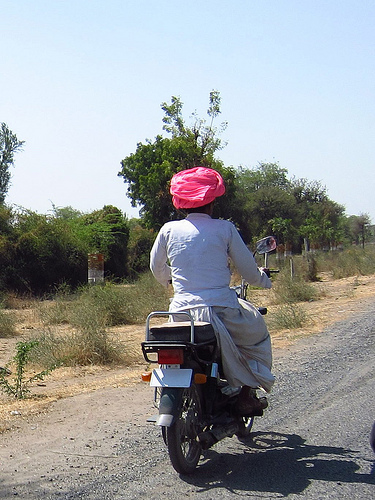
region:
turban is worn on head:
[167, 165, 225, 211]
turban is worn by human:
[167, 165, 226, 211]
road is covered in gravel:
[0, 297, 371, 498]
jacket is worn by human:
[146, 213, 269, 307]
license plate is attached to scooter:
[149, 368, 192, 386]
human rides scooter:
[147, 165, 278, 400]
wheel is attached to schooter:
[157, 388, 205, 477]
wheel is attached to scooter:
[229, 371, 259, 441]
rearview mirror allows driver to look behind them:
[256, 232, 275, 255]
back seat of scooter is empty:
[145, 311, 210, 347]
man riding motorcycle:
[136, 168, 276, 412]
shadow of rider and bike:
[214, 415, 349, 499]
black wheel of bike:
[165, 375, 212, 472]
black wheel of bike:
[238, 414, 261, 434]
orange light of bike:
[192, 371, 205, 382]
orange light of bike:
[140, 373, 156, 380]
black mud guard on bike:
[151, 385, 180, 428]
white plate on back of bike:
[148, 366, 195, 388]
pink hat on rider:
[167, 168, 224, 209]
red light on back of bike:
[156, 350, 183, 362]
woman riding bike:
[133, 149, 253, 456]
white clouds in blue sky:
[250, 111, 282, 133]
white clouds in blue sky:
[235, 23, 265, 56]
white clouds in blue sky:
[65, 142, 107, 182]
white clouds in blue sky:
[82, 45, 112, 66]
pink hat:
[162, 160, 230, 213]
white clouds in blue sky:
[257, 44, 289, 61]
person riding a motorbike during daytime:
[106, 164, 307, 468]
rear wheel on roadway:
[153, 423, 216, 480]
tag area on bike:
[136, 357, 206, 391]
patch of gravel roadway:
[287, 327, 351, 400]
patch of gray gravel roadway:
[276, 315, 359, 398]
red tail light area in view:
[147, 343, 185, 366]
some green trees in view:
[14, 208, 122, 246]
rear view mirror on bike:
[251, 227, 287, 266]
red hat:
[163, 157, 216, 208]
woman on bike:
[123, 151, 259, 478]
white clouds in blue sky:
[48, 46, 80, 65]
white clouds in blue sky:
[265, 51, 319, 113]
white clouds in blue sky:
[51, 99, 87, 127]